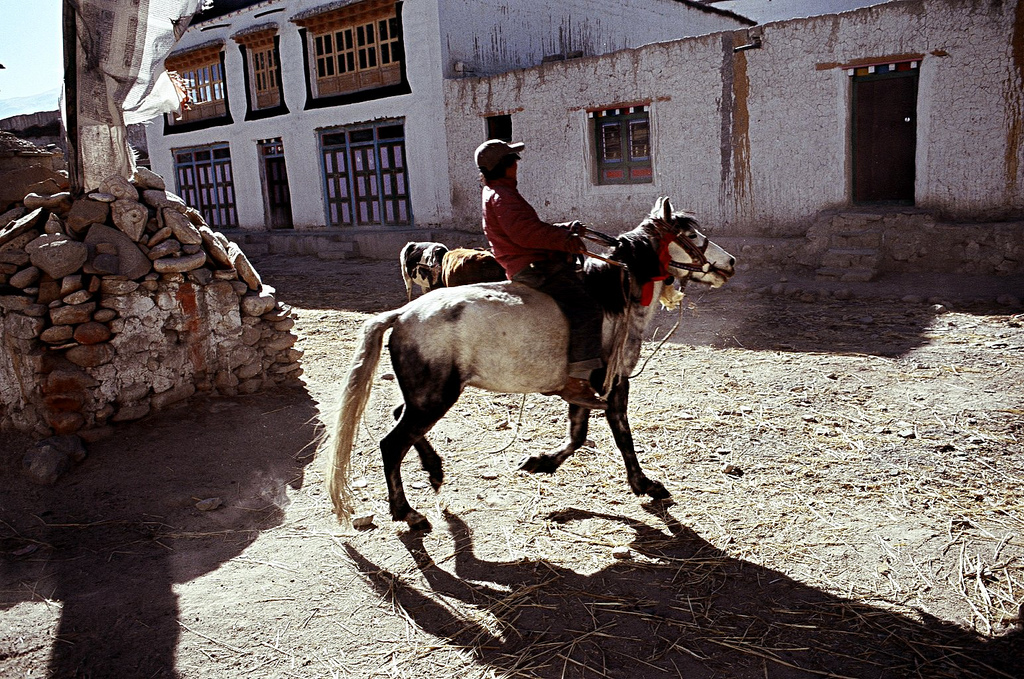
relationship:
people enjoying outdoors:
[402, 122, 617, 321] [8, 33, 983, 558]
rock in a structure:
[38, 236, 91, 265] [13, 284, 301, 416]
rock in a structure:
[36, 238, 89, 273] [13, 284, 301, 416]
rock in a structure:
[36, 232, 101, 272] [13, 284, 301, 416]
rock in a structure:
[41, 229, 85, 273] [155, 35, 339, 226]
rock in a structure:
[38, 240, 90, 273] [162, 24, 314, 221]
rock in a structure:
[36, 227, 88, 271] [166, 27, 342, 226]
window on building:
[299, 104, 444, 247] [102, 13, 990, 277]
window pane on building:
[240, 45, 290, 110] [146, 2, 1015, 231]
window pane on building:
[241, 26, 281, 109] [146, 2, 1015, 231]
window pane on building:
[165, 39, 224, 117] [146, 2, 1015, 231]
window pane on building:
[158, 43, 236, 134] [146, 2, 1015, 231]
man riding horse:
[472, 142, 622, 406] [329, 197, 738, 528]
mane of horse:
[603, 203, 699, 273] [329, 197, 738, 528]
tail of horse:
[323, 313, 397, 523] [329, 197, 738, 528]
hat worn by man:
[467, 138, 530, 164] [474, 132, 613, 413]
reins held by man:
[588, 212, 727, 290] [472, 142, 622, 406]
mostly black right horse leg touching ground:
[618, 401, 696, 520] [212, 494, 986, 679]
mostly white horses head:
[560, 164, 753, 335] [652, 233, 704, 270]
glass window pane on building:
[357, 105, 379, 110] [281, 205, 379, 212]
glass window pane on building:
[356, 205, 391, 221] [754, 213, 828, 250]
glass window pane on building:
[346, 110, 394, 130] [214, 211, 243, 229]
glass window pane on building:
[363, 103, 396, 106] [276, 203, 329, 232]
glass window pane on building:
[316, 203, 362, 251] [289, 274, 307, 329]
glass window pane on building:
[244, 103, 273, 108] [205, 205, 227, 212]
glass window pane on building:
[199, 205, 239, 245] [257, 250, 320, 302]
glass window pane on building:
[599, 146, 621, 179] [735, 213, 770, 227]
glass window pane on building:
[624, 123, 650, 152] [741, 211, 856, 225]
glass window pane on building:
[173, 123, 193, 152] [277, 203, 304, 208]